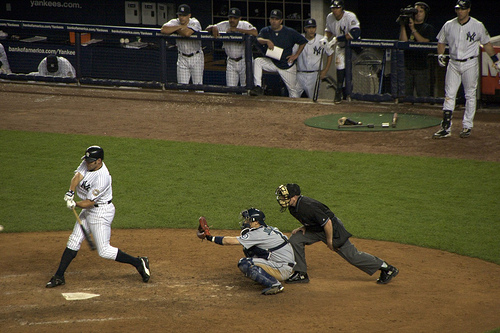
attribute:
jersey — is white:
[61, 172, 135, 209]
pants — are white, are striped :
[69, 209, 119, 264]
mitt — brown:
[196, 216, 213, 243]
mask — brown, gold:
[76, 144, 116, 181]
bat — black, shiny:
[305, 43, 327, 111]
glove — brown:
[187, 201, 222, 248]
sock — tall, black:
[53, 246, 78, 276]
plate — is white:
[61, 291, 99, 298]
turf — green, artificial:
[140, 151, 355, 236]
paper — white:
[264, 44, 289, 66]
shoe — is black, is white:
[128, 251, 156, 282]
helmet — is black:
[78, 143, 117, 172]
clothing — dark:
[297, 209, 367, 257]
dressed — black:
[298, 195, 382, 282]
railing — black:
[74, 25, 180, 89]